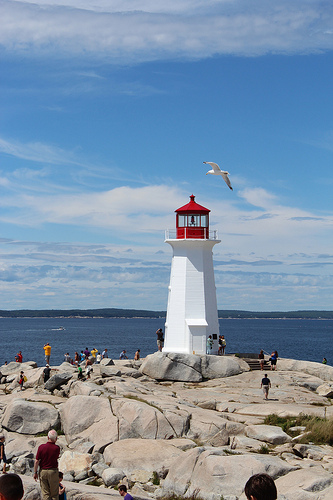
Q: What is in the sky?
A: Bird.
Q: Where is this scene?
A: Beachside.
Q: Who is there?
A: Beachgoers.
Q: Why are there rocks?
A: Natural landscape.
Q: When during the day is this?
A: Afternoon.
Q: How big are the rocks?
A: Huge.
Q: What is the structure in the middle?
A: Lighthouse.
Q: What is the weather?
A: Fair.